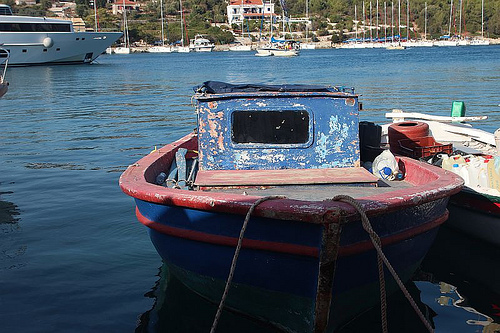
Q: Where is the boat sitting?
A: In the water.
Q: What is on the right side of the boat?
A: A rope.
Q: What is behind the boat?
A: Large body of water.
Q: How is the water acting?
A: Calm.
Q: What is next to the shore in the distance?
A: Docked boats.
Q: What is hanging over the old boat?
A: A rope.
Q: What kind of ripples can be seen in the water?
A: Small ripples.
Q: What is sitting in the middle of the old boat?
A: A piece of wood.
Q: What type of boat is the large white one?
A: A yacht.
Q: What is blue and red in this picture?
A: An old boat.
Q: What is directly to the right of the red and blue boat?
A: A white boat full of stuff.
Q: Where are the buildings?
A: In the distance by the beach.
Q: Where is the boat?
A: Floating in the water.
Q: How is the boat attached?
A: With a rope.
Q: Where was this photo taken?
A: Outside by the water.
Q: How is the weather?
A: Clear and sunny.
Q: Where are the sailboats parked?
A: Along the other side of the water.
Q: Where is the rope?
A: Attached to the boat.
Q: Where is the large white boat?
A: On the left side.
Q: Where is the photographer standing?
A: In the shade.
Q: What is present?
A: Boats.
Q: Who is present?
A: Nobody.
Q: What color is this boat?
A: Blue.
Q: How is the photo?
A: Clear.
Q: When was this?
A: Daytime.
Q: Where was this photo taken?
A: In the harbor by the dirty boat.